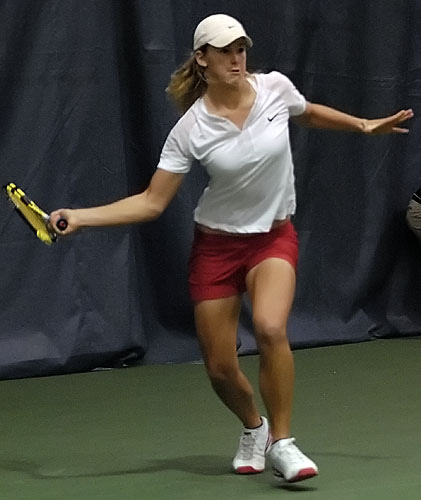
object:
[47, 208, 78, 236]
hand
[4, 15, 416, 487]
tennis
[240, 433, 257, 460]
laces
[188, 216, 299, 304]
shorts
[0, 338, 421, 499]
ground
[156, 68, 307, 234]
shirt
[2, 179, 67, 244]
tennis racquet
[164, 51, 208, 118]
hair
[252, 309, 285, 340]
left knee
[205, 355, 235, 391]
right knee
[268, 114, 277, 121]
logo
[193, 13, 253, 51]
hat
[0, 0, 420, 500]
tennis court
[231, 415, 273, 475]
foot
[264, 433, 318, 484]
foot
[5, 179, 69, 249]
racket